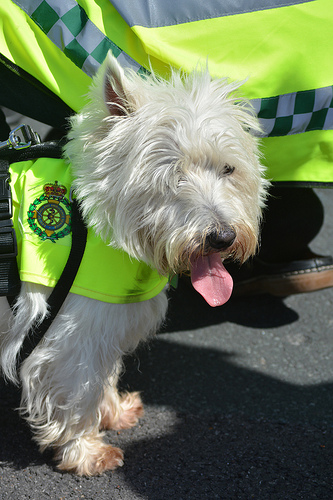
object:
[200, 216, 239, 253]
nose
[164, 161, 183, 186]
eyes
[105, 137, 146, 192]
fur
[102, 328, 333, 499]
shadow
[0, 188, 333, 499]
ground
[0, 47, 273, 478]
dog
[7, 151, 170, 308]
cloth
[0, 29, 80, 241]
back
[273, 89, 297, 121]
square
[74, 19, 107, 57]
square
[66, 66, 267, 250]
hair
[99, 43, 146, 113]
ear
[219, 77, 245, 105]
ear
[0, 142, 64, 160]
leash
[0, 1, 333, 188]
cloth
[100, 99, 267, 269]
face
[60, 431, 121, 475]
feet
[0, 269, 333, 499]
pavement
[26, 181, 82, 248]
graphic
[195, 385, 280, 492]
concrete